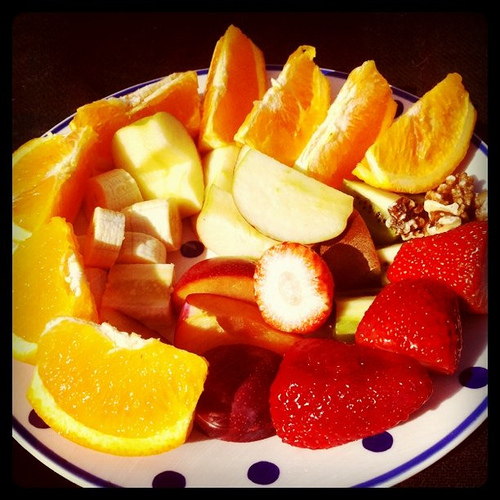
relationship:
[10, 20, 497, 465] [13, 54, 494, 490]
fruit on plate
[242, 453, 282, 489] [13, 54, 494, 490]
dots on plate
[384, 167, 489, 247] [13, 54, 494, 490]
granola on plate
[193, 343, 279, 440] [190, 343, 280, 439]
skin of a apple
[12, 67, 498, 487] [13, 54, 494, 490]
ring on a plate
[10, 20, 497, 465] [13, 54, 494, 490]
fruit on a plate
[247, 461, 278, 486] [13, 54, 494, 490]
dots on a plate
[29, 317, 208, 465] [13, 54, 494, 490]
fruit on a plate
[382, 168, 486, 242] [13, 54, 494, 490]
walnuts on a plate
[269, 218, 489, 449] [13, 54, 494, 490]
strawberries on a plate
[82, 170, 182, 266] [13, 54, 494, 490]
bananas on a plate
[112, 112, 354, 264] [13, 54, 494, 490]
apple on a plate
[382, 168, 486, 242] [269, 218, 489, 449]
walnuts beside strawberries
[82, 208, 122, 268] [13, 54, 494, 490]
banana on a plate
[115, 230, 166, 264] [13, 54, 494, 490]
banana on a plate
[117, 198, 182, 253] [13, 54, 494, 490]
bananas on a plate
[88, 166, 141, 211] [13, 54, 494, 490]
banana on a plate